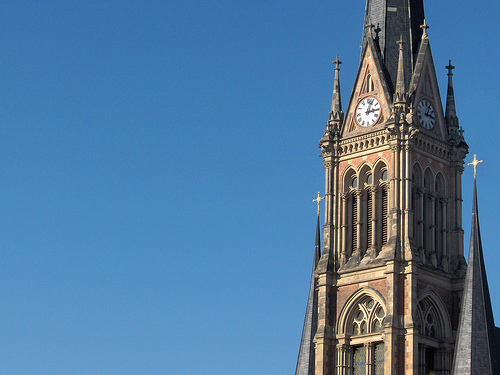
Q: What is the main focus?
A: Clock tower.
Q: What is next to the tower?
A: Spires.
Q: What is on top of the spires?
A: Crosses.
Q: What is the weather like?
A: Clear.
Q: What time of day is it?
A: Afternoon.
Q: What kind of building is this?
A: Church.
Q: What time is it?
A: 3:02.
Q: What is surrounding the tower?
A: Sky.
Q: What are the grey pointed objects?
A: Steeples.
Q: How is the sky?
A: Very blue and clear.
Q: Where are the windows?
A: On the church tower.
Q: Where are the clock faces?
A: Near the top of the steeple.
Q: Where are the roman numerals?
A: On the clock faces.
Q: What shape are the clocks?
A: Round.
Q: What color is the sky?
A: Blue.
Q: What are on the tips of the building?
A: Crosses.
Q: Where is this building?
A: In the sky.